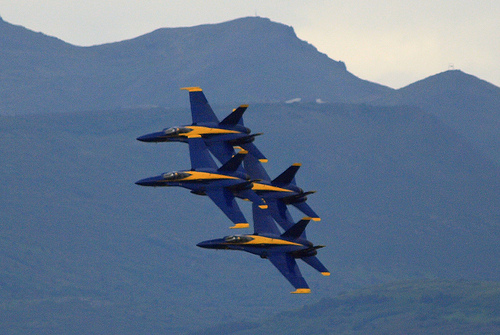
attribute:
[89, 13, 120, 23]
clouds — white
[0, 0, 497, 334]
sky — blue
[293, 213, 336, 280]
wing — back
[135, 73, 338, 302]
planes — grouped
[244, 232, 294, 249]
strip — yellow